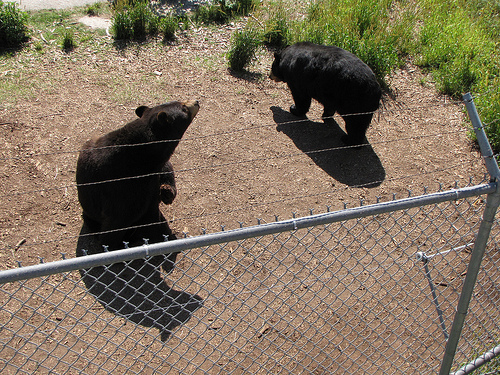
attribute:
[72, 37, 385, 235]
bear — black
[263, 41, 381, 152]
bear — brown, walking, black, large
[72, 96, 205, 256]
bear — brown, black, large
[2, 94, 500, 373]
fencing — aluminum, metal, chain link, wired, protection, mesh, linked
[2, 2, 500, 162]
grass — green, tall, bright green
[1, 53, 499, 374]
soil — dry, dusty, brown, grass less, covered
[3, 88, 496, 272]
wire — barbed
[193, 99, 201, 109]
snout — light brown, black